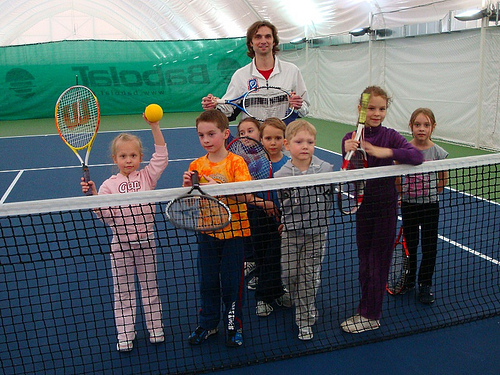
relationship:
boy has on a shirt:
[183, 107, 251, 341] [224, 156, 244, 173]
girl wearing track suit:
[339, 84, 424, 335] [343, 114, 416, 213]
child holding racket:
[81, 103, 169, 352] [54, 83, 102, 198]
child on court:
[81, 103, 169, 352] [3, 114, 484, 354]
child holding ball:
[81, 103, 169, 352] [136, 100, 164, 124]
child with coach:
[81, 103, 169, 352] [199, 20, 308, 142]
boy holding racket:
[74, 100, 190, 342] [48, 75, 108, 218]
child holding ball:
[81, 103, 169, 352] [145, 105, 161, 118]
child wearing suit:
[81, 103, 169, 352] [91, 151, 165, 344]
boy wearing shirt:
[183, 107, 251, 341] [181, 154, 256, 237]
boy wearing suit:
[279, 118, 332, 340] [275, 164, 338, 314]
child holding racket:
[81, 103, 169, 352] [56, 87, 99, 177]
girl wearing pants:
[403, 111, 445, 301] [401, 201, 440, 294]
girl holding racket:
[401, 106, 445, 300] [389, 229, 409, 290]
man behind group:
[200, 25, 307, 121] [101, 93, 445, 339]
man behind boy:
[200, 25, 307, 121] [183, 107, 251, 341]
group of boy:
[101, 93, 445, 339] [183, 107, 251, 341]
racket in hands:
[240, 85, 292, 119] [202, 87, 301, 105]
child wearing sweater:
[81, 103, 169, 352] [96, 149, 170, 234]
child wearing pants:
[81, 103, 169, 352] [107, 232, 166, 343]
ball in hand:
[143, 102, 164, 122] [143, 111, 164, 126]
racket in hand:
[54, 83, 102, 198] [78, 179, 91, 194]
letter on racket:
[63, 101, 95, 126] [50, 80, 100, 170]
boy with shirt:
[183, 107, 251, 341] [180, 160, 253, 232]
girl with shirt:
[339, 84, 424, 335] [343, 131, 415, 198]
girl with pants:
[339, 84, 424, 335] [354, 193, 394, 314]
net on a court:
[7, 210, 412, 343] [3, 114, 484, 354]